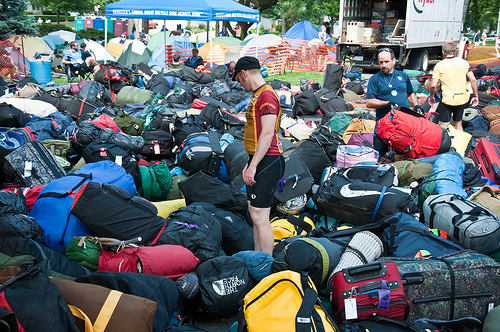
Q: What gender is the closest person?
A: Male.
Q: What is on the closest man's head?
A: Cap.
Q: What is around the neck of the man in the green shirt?
A: Necklace.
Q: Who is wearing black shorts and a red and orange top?
A: The closest man.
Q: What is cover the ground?
A: Duffle bags and suitcases.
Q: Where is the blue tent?
A: Background on the left.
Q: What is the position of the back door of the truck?
A: Raised.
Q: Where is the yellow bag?
A: Bottom in the middle.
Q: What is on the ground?
A: Bags.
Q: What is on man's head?
A: Black hat.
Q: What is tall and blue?
A: Tarp.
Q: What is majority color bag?
A: Black.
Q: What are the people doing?
A: Looking through the luggage.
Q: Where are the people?
A: At an activity.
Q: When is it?
A: Daytime.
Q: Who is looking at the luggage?
A: The people.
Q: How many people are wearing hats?
A: One.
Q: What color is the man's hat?
A: Black.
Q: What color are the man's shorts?
A: Black.